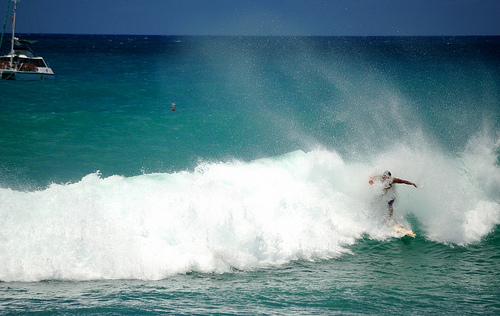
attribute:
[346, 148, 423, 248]
surfer — wet, green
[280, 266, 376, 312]
water — green, white, blue, deep, teal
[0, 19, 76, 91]
boat — white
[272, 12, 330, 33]
sky — blue, clear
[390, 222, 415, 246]
board — white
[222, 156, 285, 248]
wave — large